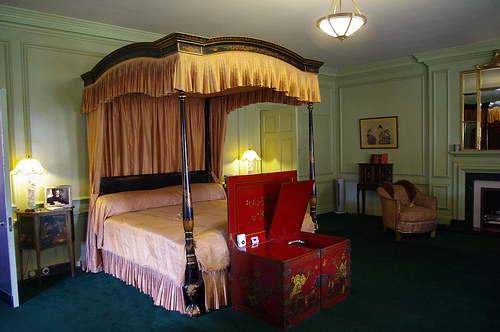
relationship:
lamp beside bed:
[15, 157, 45, 208] [86, 179, 314, 307]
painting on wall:
[358, 120, 399, 149] [317, 37, 494, 225]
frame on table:
[47, 185, 74, 208] [19, 210, 76, 280]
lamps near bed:
[15, 148, 260, 208] [86, 179, 314, 307]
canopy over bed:
[89, 31, 317, 120] [86, 179, 314, 307]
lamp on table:
[15, 157, 45, 208] [19, 210, 76, 280]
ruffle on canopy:
[90, 60, 320, 113] [89, 31, 317, 120]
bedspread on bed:
[101, 198, 235, 275] [86, 179, 314, 307]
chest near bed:
[223, 164, 359, 322] [86, 179, 314, 307]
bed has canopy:
[86, 179, 314, 307] [89, 31, 317, 120]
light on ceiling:
[317, 19, 364, 41] [3, 3, 500, 68]